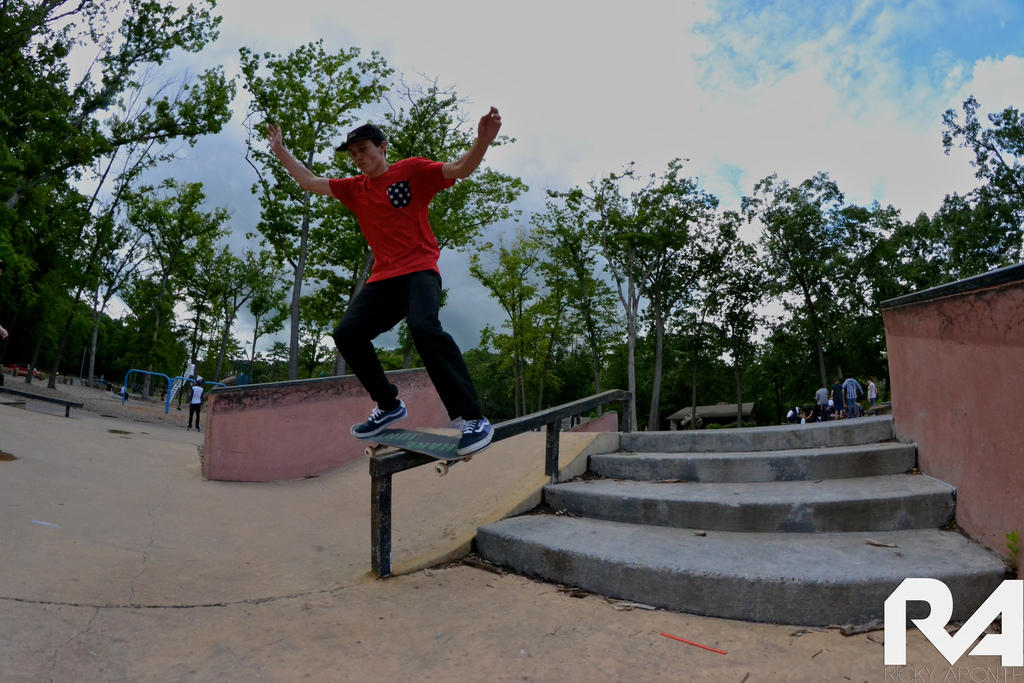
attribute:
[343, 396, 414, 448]
shoe — black, white, athletic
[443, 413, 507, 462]
shoe — athletic, black, white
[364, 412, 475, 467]
skateboard — green